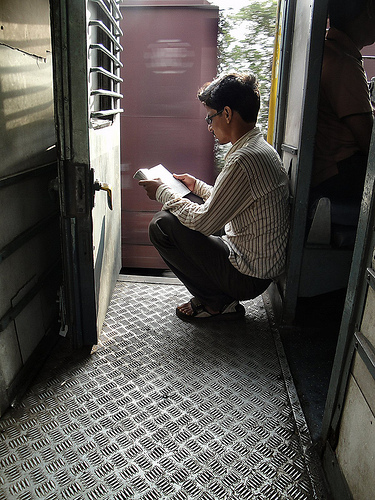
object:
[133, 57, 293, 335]
man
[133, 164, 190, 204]
book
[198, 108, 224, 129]
eyeglasses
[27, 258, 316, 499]
floor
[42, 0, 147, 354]
door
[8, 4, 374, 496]
train car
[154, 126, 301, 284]
shirt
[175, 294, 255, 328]
sandals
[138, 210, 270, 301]
dark pants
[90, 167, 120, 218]
handle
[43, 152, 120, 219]
lock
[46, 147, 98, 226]
latch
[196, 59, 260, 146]
head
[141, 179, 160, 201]
hands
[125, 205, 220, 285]
knees bent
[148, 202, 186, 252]
knee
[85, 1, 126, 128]
window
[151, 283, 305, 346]
seat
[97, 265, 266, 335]
door step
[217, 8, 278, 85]
trees